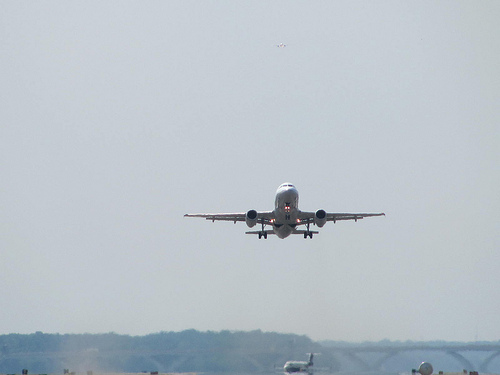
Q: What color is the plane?
A: White.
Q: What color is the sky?
A: Gray.